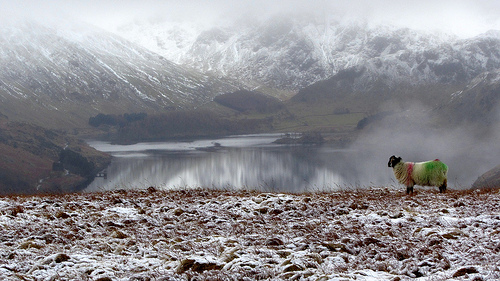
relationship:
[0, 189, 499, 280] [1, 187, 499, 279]
frost on ground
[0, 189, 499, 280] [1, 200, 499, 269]
snow on grass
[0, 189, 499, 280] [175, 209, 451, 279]
snow on rocks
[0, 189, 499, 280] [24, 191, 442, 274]
ice on grass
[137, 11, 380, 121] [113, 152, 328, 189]
mountains has reflection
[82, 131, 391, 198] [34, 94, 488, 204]
lake on bottom of valley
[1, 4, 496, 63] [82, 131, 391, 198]
mist rising on lake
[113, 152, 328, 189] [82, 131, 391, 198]
reflection on lake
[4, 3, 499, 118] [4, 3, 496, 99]
mountain covered in snow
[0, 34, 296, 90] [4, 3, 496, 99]
ridges covered in snow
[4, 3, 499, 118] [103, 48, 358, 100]
mountian has smooth slope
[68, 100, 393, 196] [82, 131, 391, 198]
land jutting out into lake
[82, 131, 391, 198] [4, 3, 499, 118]
lake at foot of mountains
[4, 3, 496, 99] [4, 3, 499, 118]
snow caped mountain range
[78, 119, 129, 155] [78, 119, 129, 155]
trail formed from trail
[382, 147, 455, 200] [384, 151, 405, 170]
sheep has black head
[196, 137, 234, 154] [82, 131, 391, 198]
island in middle of lake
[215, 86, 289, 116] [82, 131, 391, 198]
plant on other side of lake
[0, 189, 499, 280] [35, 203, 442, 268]
snow covered brown rocks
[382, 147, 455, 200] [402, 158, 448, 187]
animal painted red, white and green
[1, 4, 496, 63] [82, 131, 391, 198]
mist over lake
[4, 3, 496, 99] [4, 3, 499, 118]
snow covered mountains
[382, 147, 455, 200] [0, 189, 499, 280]
sheep on hill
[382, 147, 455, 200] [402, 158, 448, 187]
sheep has wool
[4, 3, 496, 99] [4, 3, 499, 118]
snow on top mountains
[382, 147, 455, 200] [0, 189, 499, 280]
animal standing on snowy grass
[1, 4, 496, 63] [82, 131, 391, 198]
fog above lake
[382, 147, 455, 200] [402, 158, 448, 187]
sheep with paint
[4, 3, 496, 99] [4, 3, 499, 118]
snow capped mountains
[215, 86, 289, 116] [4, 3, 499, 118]
trees in background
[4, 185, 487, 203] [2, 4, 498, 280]
grass in winter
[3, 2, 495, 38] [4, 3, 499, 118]
clouds covering mountain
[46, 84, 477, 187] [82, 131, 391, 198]
fog covering lake